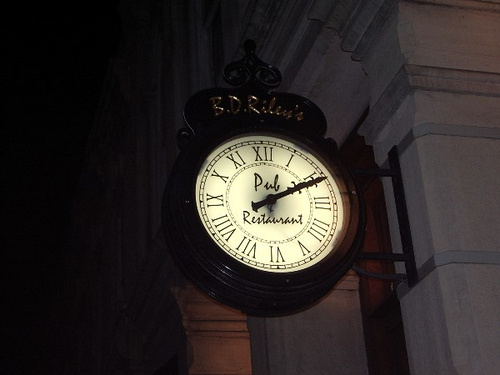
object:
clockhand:
[251, 177, 328, 213]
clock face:
[194, 136, 343, 276]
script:
[243, 172, 303, 224]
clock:
[159, 65, 369, 317]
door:
[343, 141, 407, 375]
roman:
[298, 240, 310, 255]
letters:
[314, 196, 332, 211]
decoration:
[223, 43, 282, 89]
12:
[252, 146, 273, 161]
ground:
[368, 162, 411, 199]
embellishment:
[213, 38, 283, 94]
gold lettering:
[211, 95, 303, 120]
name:
[213, 95, 304, 121]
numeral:
[270, 246, 285, 263]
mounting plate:
[344, 146, 418, 289]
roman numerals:
[286, 154, 294, 167]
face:
[194, 135, 344, 272]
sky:
[0, 0, 124, 375]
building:
[31, 2, 500, 375]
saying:
[243, 173, 302, 225]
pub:
[95, 0, 500, 375]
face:
[194, 133, 349, 274]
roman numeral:
[211, 214, 236, 241]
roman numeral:
[237, 236, 257, 258]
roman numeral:
[308, 219, 330, 242]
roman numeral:
[207, 193, 224, 207]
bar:
[349, 144, 418, 288]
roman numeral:
[252, 146, 273, 161]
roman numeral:
[314, 196, 331, 211]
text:
[243, 172, 302, 224]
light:
[183, 299, 252, 365]